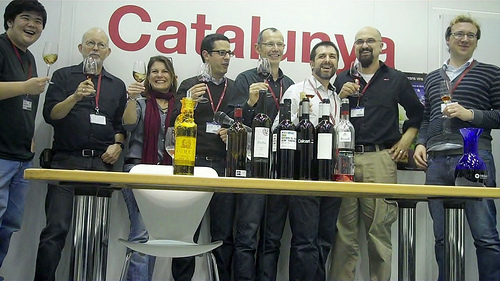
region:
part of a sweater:
[466, 77, 492, 108]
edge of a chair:
[158, 234, 186, 257]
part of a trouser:
[264, 225, 288, 258]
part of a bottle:
[283, 145, 300, 169]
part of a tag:
[203, 119, 223, 139]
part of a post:
[448, 225, 463, 250]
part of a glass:
[133, 64, 143, 81]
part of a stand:
[441, 206, 458, 248]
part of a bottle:
[290, 145, 319, 170]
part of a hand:
[255, 80, 272, 101]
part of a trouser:
[356, 215, 396, 257]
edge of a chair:
[167, 241, 199, 264]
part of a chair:
[166, 212, 189, 234]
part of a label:
[256, 137, 271, 157]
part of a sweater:
[426, 83, 439, 130]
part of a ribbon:
[216, 92, 228, 104]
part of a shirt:
[70, 115, 90, 133]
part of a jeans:
[477, 225, 493, 235]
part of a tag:
[93, 120, 105, 138]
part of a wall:
[13, 204, 37, 232]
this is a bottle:
[173, 96, 199, 174]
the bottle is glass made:
[228, 132, 243, 162]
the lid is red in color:
[233, 108, 243, 116]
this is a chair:
[135, 196, 206, 273]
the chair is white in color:
[162, 202, 176, 224]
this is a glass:
[43, 43, 58, 64]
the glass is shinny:
[85, 60, 95, 70]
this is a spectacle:
[218, 48, 238, 55]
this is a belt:
[353, 145, 373, 152]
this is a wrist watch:
[116, 140, 128, 147]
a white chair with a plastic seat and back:
[118, 155, 224, 280]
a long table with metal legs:
[17, 162, 495, 278]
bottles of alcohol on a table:
[155, 80, 365, 192]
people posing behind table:
[2, 0, 493, 271]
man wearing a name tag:
[192, 30, 228, 136]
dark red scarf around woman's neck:
[135, 45, 190, 170]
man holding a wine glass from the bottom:
[0, 7, 63, 112]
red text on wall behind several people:
[93, 0, 404, 90]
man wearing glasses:
[345, 23, 380, 55]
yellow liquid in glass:
[127, 54, 149, 88]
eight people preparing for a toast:
[3, 4, 498, 271]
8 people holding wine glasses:
[2, 1, 498, 268]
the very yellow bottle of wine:
[157, 90, 207, 191]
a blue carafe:
[450, 118, 496, 198]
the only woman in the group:
[122, 51, 183, 273]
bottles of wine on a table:
[160, 90, 389, 194]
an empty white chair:
[109, 161, 226, 278]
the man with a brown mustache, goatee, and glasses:
[340, 20, 417, 277]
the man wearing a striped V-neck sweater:
[425, 13, 497, 277]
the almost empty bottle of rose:
[335, 96, 361, 188]